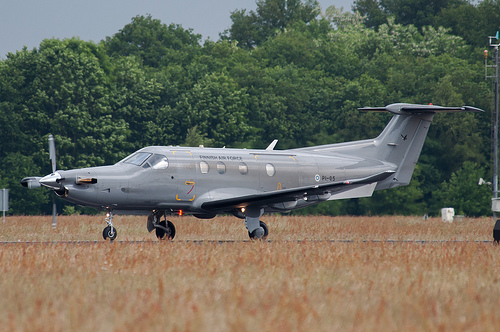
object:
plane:
[18, 102, 500, 241]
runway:
[37, 200, 480, 260]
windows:
[122, 149, 170, 173]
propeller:
[39, 166, 62, 191]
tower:
[481, 23, 499, 217]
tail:
[373, 87, 493, 188]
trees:
[0, 0, 489, 209]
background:
[0, 31, 500, 214]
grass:
[0, 215, 500, 332]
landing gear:
[101, 200, 289, 241]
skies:
[0, 0, 272, 41]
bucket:
[438, 207, 454, 223]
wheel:
[247, 218, 269, 244]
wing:
[195, 171, 396, 206]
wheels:
[102, 203, 267, 239]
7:
[183, 182, 195, 196]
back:
[140, 144, 427, 174]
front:
[23, 152, 180, 236]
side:
[152, 152, 358, 180]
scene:
[25, 10, 486, 310]